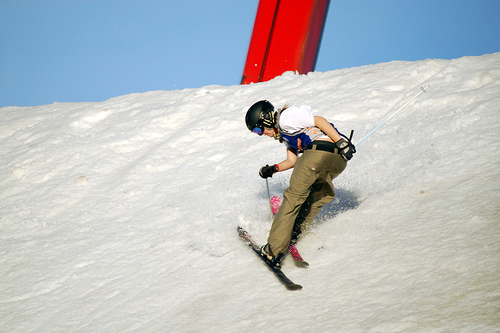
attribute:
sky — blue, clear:
[1, 3, 497, 108]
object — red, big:
[242, 0, 329, 84]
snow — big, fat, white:
[3, 53, 496, 332]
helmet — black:
[245, 99, 272, 131]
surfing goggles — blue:
[251, 122, 265, 136]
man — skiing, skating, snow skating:
[245, 100, 357, 269]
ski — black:
[238, 223, 302, 292]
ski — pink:
[272, 195, 308, 270]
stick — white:
[265, 177, 273, 201]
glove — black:
[339, 138, 356, 161]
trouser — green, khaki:
[266, 150, 348, 268]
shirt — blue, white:
[273, 109, 330, 151]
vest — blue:
[277, 129, 313, 150]